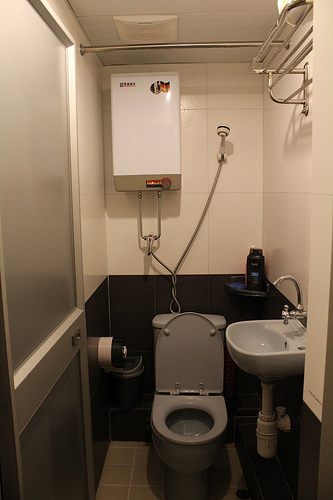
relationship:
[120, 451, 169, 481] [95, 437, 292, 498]
tiles on floor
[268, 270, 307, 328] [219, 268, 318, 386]
faucet over sink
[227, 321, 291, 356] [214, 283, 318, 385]
bowl of sink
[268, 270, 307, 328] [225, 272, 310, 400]
faucet of sink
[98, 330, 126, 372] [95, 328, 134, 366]
towel inside of holder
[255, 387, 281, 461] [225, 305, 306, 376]
drainage pipe are underneath sink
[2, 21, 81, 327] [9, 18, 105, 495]
glass attached to door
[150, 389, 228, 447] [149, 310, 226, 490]
seat on toilet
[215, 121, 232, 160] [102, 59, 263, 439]
shower head on wall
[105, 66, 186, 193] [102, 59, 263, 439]
box on wall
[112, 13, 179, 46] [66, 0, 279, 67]
fan vent on ceiling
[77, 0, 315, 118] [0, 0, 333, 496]
rods on walls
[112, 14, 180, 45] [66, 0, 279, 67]
vent on ceiling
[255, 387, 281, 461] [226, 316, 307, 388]
drainage pipe below sink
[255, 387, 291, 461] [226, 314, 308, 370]
drainage pipe on sink